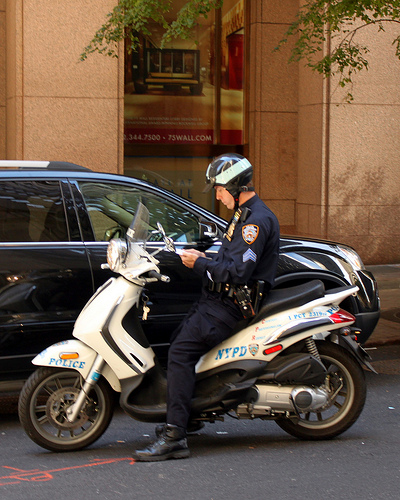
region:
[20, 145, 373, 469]
police officer on a cycle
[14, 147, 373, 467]
officer sitting on a cycle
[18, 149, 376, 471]
officer wearing a helmet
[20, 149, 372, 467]
police officer wearing a helmet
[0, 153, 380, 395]
crossover vehicle beside a policeman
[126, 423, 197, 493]
left fot of a police officer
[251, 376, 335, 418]
muffler of a motorcycle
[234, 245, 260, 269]
sergeant stripes on a sleeve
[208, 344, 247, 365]
sticker that indicates a city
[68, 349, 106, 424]
shock absorber on the cycle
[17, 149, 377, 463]
a policeman on a motorcycle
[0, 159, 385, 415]
a black car parked on street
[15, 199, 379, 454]
a white police motorcycle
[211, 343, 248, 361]
blue letters on motorcycle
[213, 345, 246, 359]
blue letters say NYPD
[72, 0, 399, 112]
two tree branches with green leaves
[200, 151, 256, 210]
a policeman wearing helmet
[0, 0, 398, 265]
a brown stone building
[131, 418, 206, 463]
a policeman wearing black shoes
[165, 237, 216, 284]
a policeman holding a white sheet of paper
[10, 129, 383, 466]
police officer on a motorcycle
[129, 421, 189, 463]
black boot on a foot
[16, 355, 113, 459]
front wheel on a motorcycle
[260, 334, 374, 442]
rear wheel on a motorcycle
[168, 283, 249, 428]
pair of black pants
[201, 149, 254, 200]
black and white motorcycle helmet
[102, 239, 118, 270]
headlight on a motorcycle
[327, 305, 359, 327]
tail light on a motorcycle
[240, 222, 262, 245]
patch on a uniform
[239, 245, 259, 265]
patch on a uniform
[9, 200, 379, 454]
whit NYPD police scooter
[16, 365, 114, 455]
front wheel of scooter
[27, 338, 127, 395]
front fender of white police scooter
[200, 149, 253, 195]
white and black safety helmet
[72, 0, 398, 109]
tree branches hanging down in front of tan stucco cement building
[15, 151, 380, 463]
policeman sitting on white NYPD scooter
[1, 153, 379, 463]
black suv getting parking ticket from policeman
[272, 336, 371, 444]
back wheel of white scooter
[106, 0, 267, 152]
glass front door of business in tan building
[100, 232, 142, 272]
headlight of white scooter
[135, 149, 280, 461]
the police officer on the bike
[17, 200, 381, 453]
the bike under the police officer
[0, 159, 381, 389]
the parked car behind the police officer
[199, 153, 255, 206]
the helmet on the head of the police officer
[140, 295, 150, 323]
the keys hanging from the bike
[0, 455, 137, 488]
the colored lines on the road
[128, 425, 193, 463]
the left foot of the police officer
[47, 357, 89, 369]
the word "POLICE" above the front tire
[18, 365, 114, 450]
the front tire of the bike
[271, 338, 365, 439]
the back tire of the bike